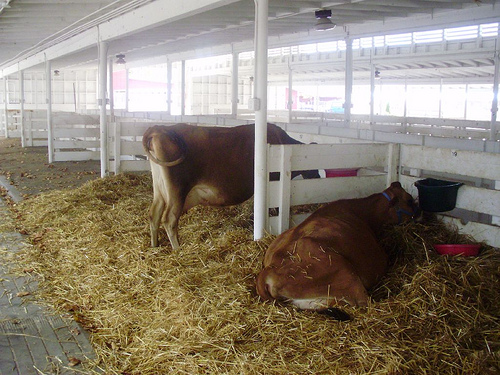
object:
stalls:
[1, 37, 103, 167]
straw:
[123, 260, 258, 354]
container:
[410, 176, 463, 214]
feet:
[145, 218, 188, 251]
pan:
[437, 232, 475, 260]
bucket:
[414, 175, 463, 220]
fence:
[264, 140, 499, 252]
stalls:
[0, 1, 496, 326]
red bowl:
[439, 237, 483, 256]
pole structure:
[90, 45, 115, 178]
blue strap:
[381, 185, 412, 229]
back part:
[2, 107, 142, 201]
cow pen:
[0, 5, 496, 370]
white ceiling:
[21, 39, 84, 71]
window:
[380, 86, 487, 118]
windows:
[70, 72, 259, 120]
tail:
[141, 124, 188, 167]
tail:
[254, 282, 352, 322]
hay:
[15, 168, 498, 372]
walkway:
[1, 183, 116, 373]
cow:
[141, 121, 321, 252]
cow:
[253, 183, 421, 317]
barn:
[2, 4, 494, 372]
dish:
[411, 172, 464, 214]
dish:
[322, 161, 360, 180]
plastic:
[416, 177, 456, 211]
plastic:
[436, 242, 479, 252]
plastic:
[326, 167, 358, 177]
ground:
[1, 145, 495, 369]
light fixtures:
[311, 9, 333, 31]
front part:
[5, 177, 495, 370]